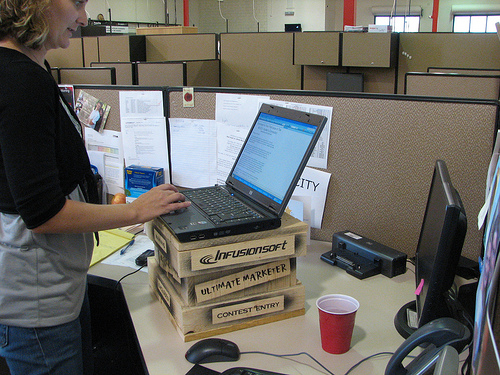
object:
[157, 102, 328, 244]
laptop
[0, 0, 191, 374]
woman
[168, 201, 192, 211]
finger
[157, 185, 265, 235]
keyboard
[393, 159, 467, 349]
monitor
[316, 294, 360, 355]
cup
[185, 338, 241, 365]
mouse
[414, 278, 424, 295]
stick note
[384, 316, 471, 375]
telephone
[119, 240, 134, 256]
pen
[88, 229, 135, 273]
notepad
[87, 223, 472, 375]
desk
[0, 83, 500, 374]
cubicles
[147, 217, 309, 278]
box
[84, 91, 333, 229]
paper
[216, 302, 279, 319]
writing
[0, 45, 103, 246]
shirt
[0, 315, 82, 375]
jeans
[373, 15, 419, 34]
window